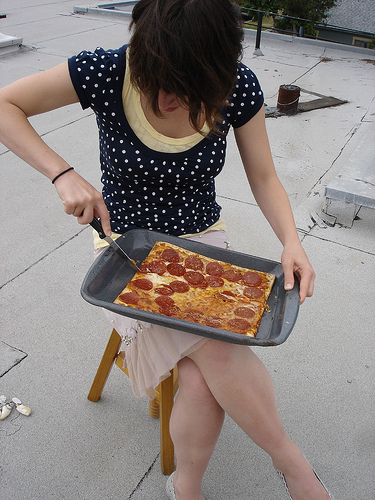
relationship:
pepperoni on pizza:
[233, 304, 255, 322] [122, 258, 267, 306]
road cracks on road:
[299, 204, 335, 244] [2, 1, 372, 495]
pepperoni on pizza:
[130, 277, 154, 293] [90, 217, 308, 339]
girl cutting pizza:
[2, 1, 332, 497] [110, 236, 277, 348]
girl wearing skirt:
[2, 1, 332, 497] [133, 341, 170, 380]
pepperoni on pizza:
[130, 277, 154, 293] [112, 238, 277, 340]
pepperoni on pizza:
[233, 304, 255, 322] [112, 238, 277, 340]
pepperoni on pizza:
[169, 262, 232, 290] [112, 238, 277, 340]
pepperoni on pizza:
[241, 271, 261, 284] [112, 238, 277, 340]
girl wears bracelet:
[2, 1, 333, 500] [49, 165, 74, 183]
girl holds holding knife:
[2, 1, 333, 500] [70, 209, 136, 266]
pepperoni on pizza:
[130, 277, 154, 293] [118, 224, 277, 346]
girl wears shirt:
[2, 1, 333, 500] [62, 43, 265, 235]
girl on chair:
[2, 1, 333, 500] [87, 325, 180, 476]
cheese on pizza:
[144, 269, 178, 285] [112, 238, 277, 340]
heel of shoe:
[165, 470, 175, 498] [164, 469, 205, 498]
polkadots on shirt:
[149, 168, 192, 193] [62, 43, 265, 235]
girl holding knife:
[2, 1, 332, 497] [96, 231, 143, 271]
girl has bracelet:
[2, 1, 333, 500] [51, 166, 73, 183]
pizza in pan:
[112, 238, 277, 340] [80, 228, 299, 345]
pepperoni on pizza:
[233, 304, 255, 322] [110, 236, 277, 348]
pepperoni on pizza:
[130, 277, 154, 293] [110, 236, 277, 348]